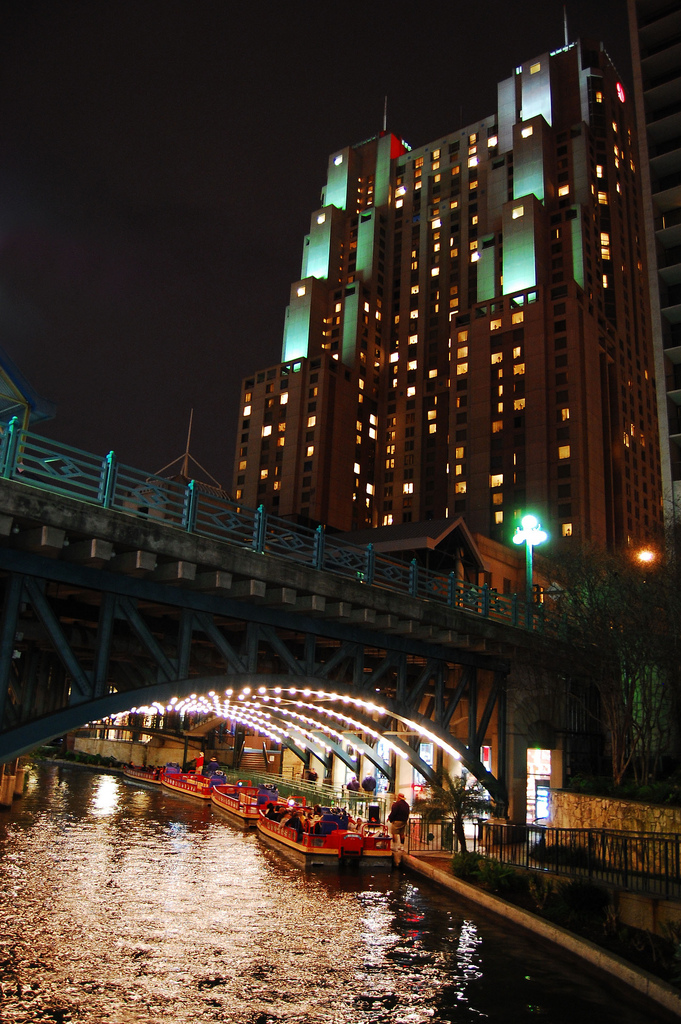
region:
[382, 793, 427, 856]
person standing on dock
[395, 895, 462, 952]
large body of water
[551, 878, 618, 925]
bushes next to water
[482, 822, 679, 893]
black gate next to water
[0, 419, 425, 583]
light blue gate above water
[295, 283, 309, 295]
window on the building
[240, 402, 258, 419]
window on the building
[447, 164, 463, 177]
window on the building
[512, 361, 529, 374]
window on the building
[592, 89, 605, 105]
window on the building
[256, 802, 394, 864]
the boat is in the water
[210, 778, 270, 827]
the boat is in the water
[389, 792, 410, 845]
the man is wearing an orange hat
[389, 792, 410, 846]
the man is wearing brown shorts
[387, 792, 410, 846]
the man is wearing a black top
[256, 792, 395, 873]
the boat is red and blue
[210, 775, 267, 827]
the boat is red blue and yellow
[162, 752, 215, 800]
the boat is red yellow and blue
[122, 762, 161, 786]
the red boat is in the water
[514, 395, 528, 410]
A window on a building.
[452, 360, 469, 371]
A window on a building.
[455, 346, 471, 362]
A window on a building.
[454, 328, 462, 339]
A window on a building.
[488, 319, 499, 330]
A window on a building.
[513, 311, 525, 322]
A window on a building.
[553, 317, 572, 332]
A window on a building.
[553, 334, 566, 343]
A window on a building.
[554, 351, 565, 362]
A window on a building.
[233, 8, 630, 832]
tall bulding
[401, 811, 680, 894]
a black gate near a sidewalk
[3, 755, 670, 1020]
a dark river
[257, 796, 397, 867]
a boat in a river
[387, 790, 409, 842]
a man standing on the sidewalk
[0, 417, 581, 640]
a green gate on a bridge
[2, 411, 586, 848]
a bridge over a river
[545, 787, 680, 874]
a rock retaining wall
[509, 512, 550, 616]
a light on a bridge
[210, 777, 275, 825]
a boat in a river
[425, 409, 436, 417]
A window on a building.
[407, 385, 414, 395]
A window on a building.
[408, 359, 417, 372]
A window on a building.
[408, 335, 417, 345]
A window on a building.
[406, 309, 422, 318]
A window on a building.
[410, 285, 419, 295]
A window on a building.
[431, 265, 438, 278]
A window on a building.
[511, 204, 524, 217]
A window on a building.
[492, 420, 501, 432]
A window on a building.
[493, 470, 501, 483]
A window on a building.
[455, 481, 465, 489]
A window on a building.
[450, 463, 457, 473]
A window on a building.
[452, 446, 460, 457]
A window on a building.